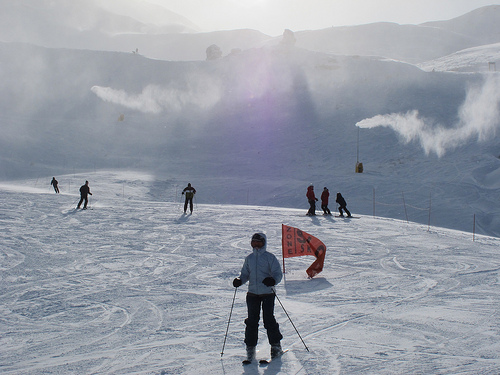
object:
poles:
[220, 286, 238, 357]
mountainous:
[0, 0, 499, 238]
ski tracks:
[0, 250, 197, 316]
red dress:
[18, 167, 149, 308]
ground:
[0, 188, 499, 375]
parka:
[238, 232, 283, 294]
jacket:
[238, 232, 283, 295]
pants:
[244, 292, 284, 346]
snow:
[2, 180, 499, 375]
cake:
[206, 225, 298, 365]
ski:
[259, 345, 290, 364]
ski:
[241, 341, 256, 364]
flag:
[282, 223, 327, 278]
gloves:
[233, 278, 242, 288]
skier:
[320, 187, 330, 215]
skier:
[336, 192, 352, 217]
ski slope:
[0, 190, 499, 373]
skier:
[305, 185, 318, 216]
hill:
[1, 0, 499, 185]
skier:
[77, 180, 93, 210]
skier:
[181, 183, 196, 212]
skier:
[50, 177, 59, 194]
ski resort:
[0, 0, 499, 375]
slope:
[0, 190, 499, 375]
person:
[236, 227, 284, 362]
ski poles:
[220, 287, 238, 358]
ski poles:
[271, 286, 310, 352]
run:
[0, 212, 498, 368]